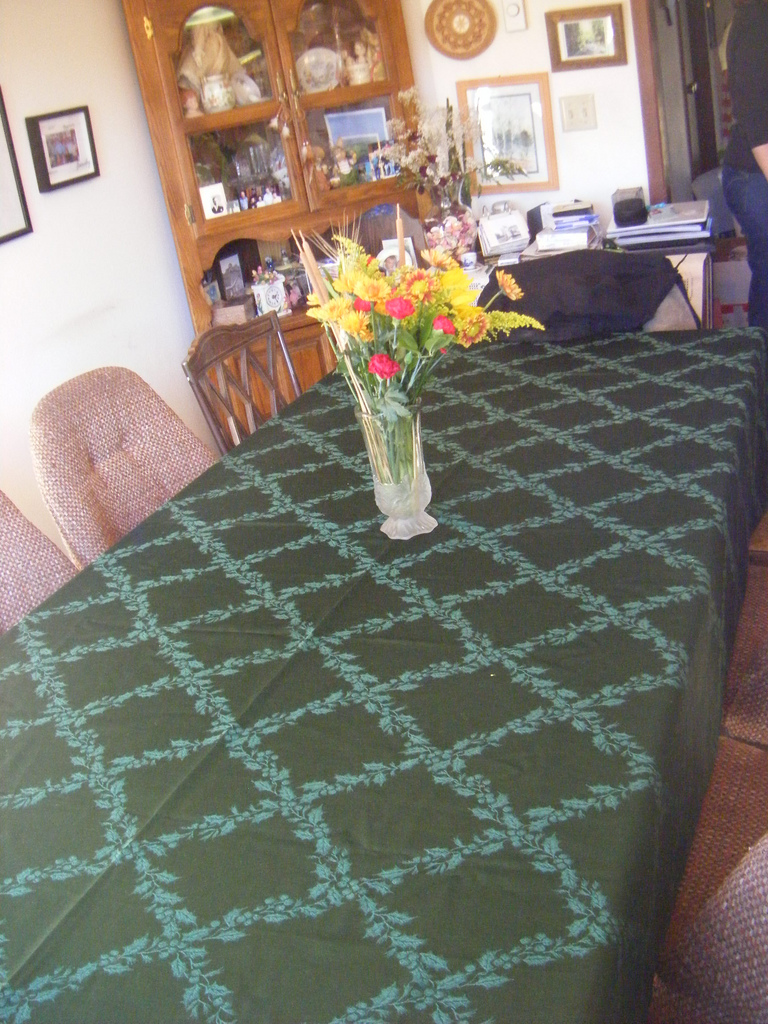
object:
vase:
[354, 397, 439, 540]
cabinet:
[123, 2, 434, 457]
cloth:
[0, 326, 767, 1022]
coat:
[479, 249, 702, 342]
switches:
[558, 95, 597, 134]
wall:
[0, 0, 668, 632]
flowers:
[305, 235, 545, 485]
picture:
[25, 106, 99, 193]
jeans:
[719, 161, 768, 326]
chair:
[181, 310, 302, 457]